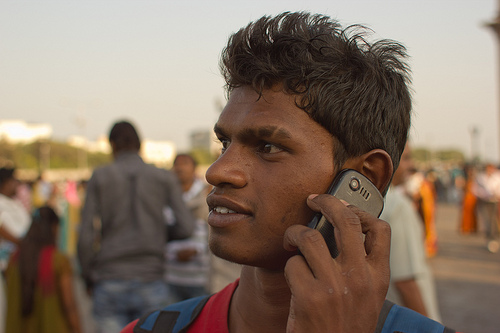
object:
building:
[0, 120, 52, 144]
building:
[70, 135, 173, 167]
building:
[193, 127, 222, 153]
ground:
[413, 203, 499, 332]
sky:
[0, 0, 499, 143]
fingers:
[305, 192, 366, 261]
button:
[349, 176, 361, 190]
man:
[114, 12, 457, 333]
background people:
[0, 118, 499, 332]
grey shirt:
[77, 153, 195, 282]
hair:
[217, 12, 410, 168]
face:
[207, 121, 336, 269]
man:
[77, 120, 191, 332]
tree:
[1, 140, 108, 168]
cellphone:
[308, 169, 384, 258]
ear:
[358, 149, 393, 195]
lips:
[208, 211, 253, 227]